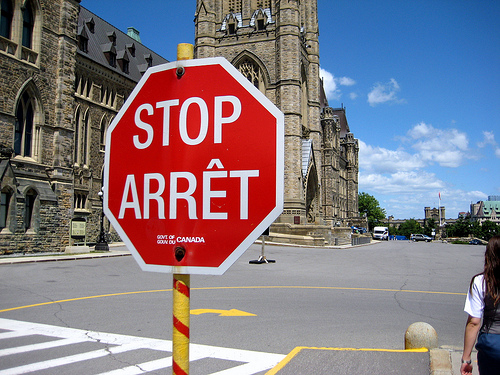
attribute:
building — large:
[198, 3, 371, 243]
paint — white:
[0, 315, 282, 373]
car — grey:
[366, 217, 388, 252]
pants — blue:
[476, 333, 498, 373]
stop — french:
[126, 93, 256, 149]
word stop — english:
[124, 92, 242, 149]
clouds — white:
[371, 148, 441, 171]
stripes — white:
[4, 316, 271, 373]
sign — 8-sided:
[82, 49, 334, 273]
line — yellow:
[0, 282, 470, 316]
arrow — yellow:
[170, 309, 310, 367]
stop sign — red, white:
[104, 53, 286, 278]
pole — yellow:
[144, 245, 254, 372]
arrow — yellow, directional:
[187, 305, 257, 317]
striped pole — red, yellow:
[174, 277, 189, 373]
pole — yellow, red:
[155, 254, 203, 356]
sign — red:
[100, 56, 284, 277]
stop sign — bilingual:
[89, 68, 300, 290]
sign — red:
[84, 46, 338, 310]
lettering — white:
[134, 91, 254, 241]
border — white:
[138, 56, 234, 71]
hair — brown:
[480, 235, 498, 275]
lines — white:
[0, 314, 283, 374]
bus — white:
[373, 222, 389, 239]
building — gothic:
[0, 1, 73, 257]